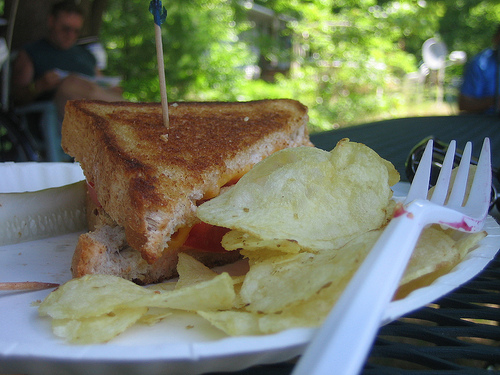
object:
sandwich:
[59, 92, 313, 289]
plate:
[2, 180, 498, 375]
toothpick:
[145, 0, 172, 132]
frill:
[142, 0, 174, 27]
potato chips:
[30, 270, 233, 324]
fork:
[288, 135, 500, 375]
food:
[391, 196, 487, 233]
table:
[0, 110, 500, 375]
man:
[12, 3, 130, 123]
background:
[1, 0, 499, 163]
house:
[0, 0, 130, 163]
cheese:
[59, 98, 312, 266]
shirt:
[459, 47, 498, 118]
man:
[456, 21, 500, 119]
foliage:
[98, 0, 500, 137]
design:
[0, 0, 499, 374]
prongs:
[402, 138, 435, 203]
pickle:
[238, 225, 456, 316]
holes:
[374, 333, 460, 349]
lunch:
[0, 93, 500, 375]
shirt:
[24, 40, 98, 103]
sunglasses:
[403, 133, 500, 217]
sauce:
[159, 220, 234, 253]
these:
[172, 10, 423, 99]